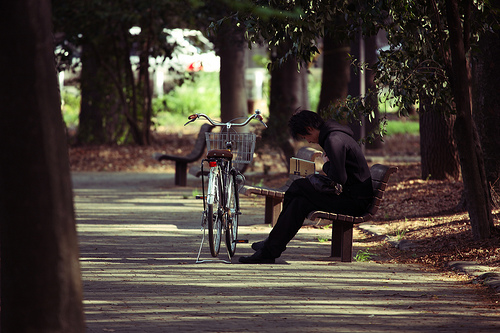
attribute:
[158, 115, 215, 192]
bench — empty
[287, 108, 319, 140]
head — bowed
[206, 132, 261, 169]
basket — metal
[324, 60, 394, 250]
trunk — tall, tree trunk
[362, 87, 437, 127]
grass — green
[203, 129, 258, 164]
basket — metal, wire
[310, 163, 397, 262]
chair — wood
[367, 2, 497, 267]
tree — small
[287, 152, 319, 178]
book — open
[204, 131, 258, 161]
basket — wire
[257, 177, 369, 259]
pants — black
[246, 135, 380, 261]
clothes — black